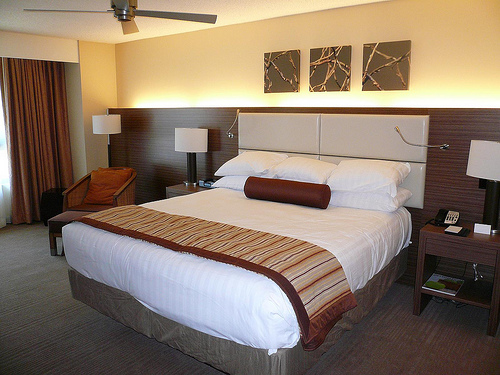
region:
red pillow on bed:
[240, 172, 343, 209]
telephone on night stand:
[429, 198, 467, 233]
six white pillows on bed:
[221, 151, 420, 208]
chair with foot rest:
[54, 167, 129, 247]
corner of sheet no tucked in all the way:
[259, 338, 293, 362]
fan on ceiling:
[58, 6, 223, 41]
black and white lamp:
[169, 118, 211, 193]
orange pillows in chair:
[88, 169, 130, 204]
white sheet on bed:
[99, 239, 209, 299]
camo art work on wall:
[250, 42, 427, 87]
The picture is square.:
[358, 37, 416, 97]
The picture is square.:
[306, 40, 358, 100]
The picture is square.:
[255, 45, 305, 96]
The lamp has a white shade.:
[462, 135, 499, 234]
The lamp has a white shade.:
[168, 118, 210, 189]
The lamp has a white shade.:
[85, 106, 134, 170]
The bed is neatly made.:
[54, 88, 435, 374]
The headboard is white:
[211, 99, 444, 241]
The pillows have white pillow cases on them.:
[193, 141, 414, 233]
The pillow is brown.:
[238, 172, 334, 213]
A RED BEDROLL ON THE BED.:
[239, 167, 341, 212]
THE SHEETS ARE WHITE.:
[135, 259, 203, 307]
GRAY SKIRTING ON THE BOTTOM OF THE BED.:
[58, 267, 276, 374]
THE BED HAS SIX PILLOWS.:
[219, 142, 409, 215]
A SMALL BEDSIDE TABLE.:
[420, 210, 499, 309]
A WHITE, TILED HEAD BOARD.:
[238, 110, 426, 165]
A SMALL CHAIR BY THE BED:
[38, 150, 135, 237]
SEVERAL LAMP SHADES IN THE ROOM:
[91, 113, 215, 157]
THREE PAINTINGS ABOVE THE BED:
[261, 73, 415, 97]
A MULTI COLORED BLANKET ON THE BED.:
[90, 200, 365, 350]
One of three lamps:
[89, 99, 127, 162]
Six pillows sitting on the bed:
[216, 146, 407, 216]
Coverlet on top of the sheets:
[56, 202, 363, 354]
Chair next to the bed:
[42, 160, 139, 216]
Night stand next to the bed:
[406, 206, 498, 328]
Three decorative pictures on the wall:
[260, 37, 420, 99]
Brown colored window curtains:
[1, 56, 75, 226]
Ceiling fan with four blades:
[32, 2, 218, 63]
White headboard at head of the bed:
[231, 109, 425, 209]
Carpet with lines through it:
[0, 216, 499, 374]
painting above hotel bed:
[263, 50, 298, 95]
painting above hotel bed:
[308, 46, 349, 92]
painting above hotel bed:
[362, 40, 410, 90]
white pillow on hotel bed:
[213, 151, 289, 176]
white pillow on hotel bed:
[210, 176, 247, 190]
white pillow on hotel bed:
[262, 156, 338, 183]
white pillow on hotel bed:
[327, 159, 408, 199]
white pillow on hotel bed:
[327, 189, 414, 210]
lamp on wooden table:
[174, 128, 208, 189]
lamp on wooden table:
[466, 137, 499, 235]